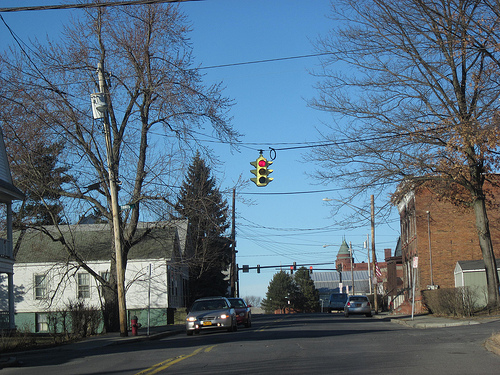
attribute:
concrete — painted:
[0, 312, 497, 373]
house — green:
[4, 205, 219, 330]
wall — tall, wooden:
[381, 127, 473, 191]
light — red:
[260, 159, 267, 168]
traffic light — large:
[288, 266, 295, 274]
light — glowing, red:
[242, 152, 274, 199]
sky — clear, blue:
[197, 15, 303, 48]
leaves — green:
[315, 40, 496, 188]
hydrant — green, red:
[123, 307, 148, 342]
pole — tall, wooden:
[93, 114, 152, 327]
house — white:
[1, 217, 190, 333]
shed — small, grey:
[451, 255, 498, 317]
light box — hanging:
[245, 150, 277, 190]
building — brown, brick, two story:
[391, 165, 497, 321]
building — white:
[0, 222, 185, 334]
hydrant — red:
[126, 313, 144, 335]